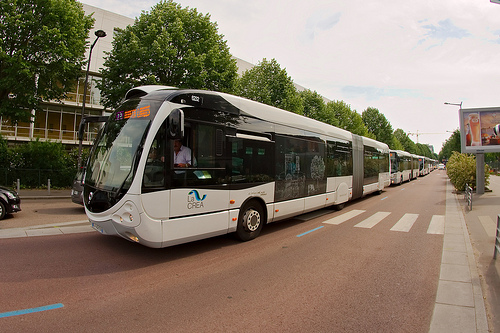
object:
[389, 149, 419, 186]
bus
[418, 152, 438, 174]
bus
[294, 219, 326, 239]
line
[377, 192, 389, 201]
line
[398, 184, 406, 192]
line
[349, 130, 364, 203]
accordian panel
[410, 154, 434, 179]
bus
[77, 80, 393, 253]
bus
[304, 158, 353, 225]
ground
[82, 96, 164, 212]
windshield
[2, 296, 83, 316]
line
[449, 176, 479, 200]
barrier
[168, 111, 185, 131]
mirror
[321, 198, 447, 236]
crosswalk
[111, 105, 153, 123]
bus destination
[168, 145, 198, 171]
shirt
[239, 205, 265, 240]
wheel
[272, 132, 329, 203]
ads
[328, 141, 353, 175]
ads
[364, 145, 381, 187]
ads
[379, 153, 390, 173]
ads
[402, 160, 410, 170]
ads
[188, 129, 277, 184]
windows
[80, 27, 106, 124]
street light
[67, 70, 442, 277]
bus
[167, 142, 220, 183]
mirror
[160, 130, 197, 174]
driver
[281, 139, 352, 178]
windows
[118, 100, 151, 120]
sign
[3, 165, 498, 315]
street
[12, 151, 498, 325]
city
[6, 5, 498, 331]
daytime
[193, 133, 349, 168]
commuters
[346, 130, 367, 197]
center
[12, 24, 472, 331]
road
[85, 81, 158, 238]
front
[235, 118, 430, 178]
passengers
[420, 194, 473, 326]
sidewalk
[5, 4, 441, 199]
trees